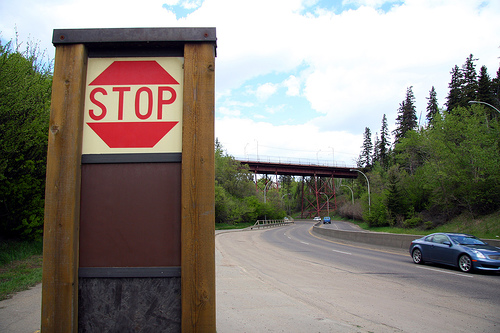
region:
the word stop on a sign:
[89, 85, 175, 120]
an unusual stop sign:
[84, 55, 183, 148]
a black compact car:
[410, 230, 498, 273]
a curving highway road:
[259, 212, 497, 317]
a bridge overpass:
[228, 151, 360, 178]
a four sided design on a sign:
[85, 119, 181, 149]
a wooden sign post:
[44, 26, 216, 331]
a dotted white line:
[332, 247, 352, 258]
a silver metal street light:
[346, 167, 372, 219]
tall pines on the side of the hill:
[354, 54, 495, 177]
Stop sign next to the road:
[83, 53, 181, 149]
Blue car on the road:
[409, 233, 499, 275]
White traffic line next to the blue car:
[415, 263, 473, 278]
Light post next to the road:
[464, 97, 499, 129]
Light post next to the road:
[347, 165, 370, 220]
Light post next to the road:
[339, 181, 355, 203]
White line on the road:
[331, 246, 351, 256]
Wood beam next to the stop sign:
[181, 43, 216, 332]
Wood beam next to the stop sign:
[38, 43, 85, 332]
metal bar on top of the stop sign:
[52, 27, 215, 44]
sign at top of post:
[75, 44, 192, 166]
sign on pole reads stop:
[75, 47, 195, 163]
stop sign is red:
[71, 54, 194, 162]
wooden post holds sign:
[23, 12, 228, 332]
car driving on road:
[399, 219, 499, 281]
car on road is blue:
[403, 216, 498, 277]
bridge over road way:
[221, 132, 367, 190]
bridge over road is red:
[226, 141, 371, 188]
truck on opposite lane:
[319, 209, 334, 226]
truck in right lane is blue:
[316, 213, 337, 230]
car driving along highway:
[38, 8, 484, 332]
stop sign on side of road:
[53, 13, 223, 331]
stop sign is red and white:
[85, 53, 185, 153]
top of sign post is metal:
[51, 20, 228, 48]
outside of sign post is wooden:
[41, 35, 219, 330]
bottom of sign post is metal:
[73, 263, 190, 330]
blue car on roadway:
[403, 210, 499, 285]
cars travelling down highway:
[275, 199, 499, 296]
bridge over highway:
[230, 131, 375, 232]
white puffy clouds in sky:
[37, 2, 499, 178]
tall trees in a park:
[355, 114, 384, 165]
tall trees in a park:
[377, 116, 394, 146]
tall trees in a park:
[400, 96, 418, 141]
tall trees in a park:
[420, 77, 450, 122]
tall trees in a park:
[448, 64, 478, 115]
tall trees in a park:
[474, 58, 497, 105]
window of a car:
[420, 225, 435, 240]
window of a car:
[431, 230, 452, 239]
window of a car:
[455, 230, 465, 248]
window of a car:
[467, 237, 482, 245]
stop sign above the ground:
[54, 51, 206, 176]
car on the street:
[390, 203, 499, 301]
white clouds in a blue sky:
[251, 32, 340, 127]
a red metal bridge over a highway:
[238, 148, 370, 249]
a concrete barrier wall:
[320, 224, 400, 250]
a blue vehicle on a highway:
[412, 225, 498, 287]